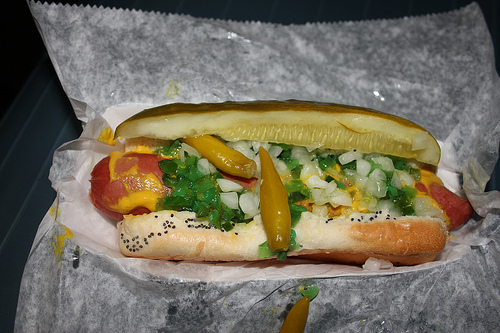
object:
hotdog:
[90, 148, 475, 232]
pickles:
[182, 136, 294, 254]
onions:
[308, 175, 352, 208]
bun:
[115, 209, 445, 266]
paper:
[14, 1, 498, 333]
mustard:
[124, 190, 149, 206]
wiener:
[90, 146, 474, 231]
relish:
[168, 157, 241, 213]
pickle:
[115, 100, 440, 169]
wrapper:
[14, 1, 498, 331]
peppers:
[259, 145, 292, 254]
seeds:
[114, 214, 186, 254]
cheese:
[116, 190, 156, 211]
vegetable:
[286, 157, 309, 206]